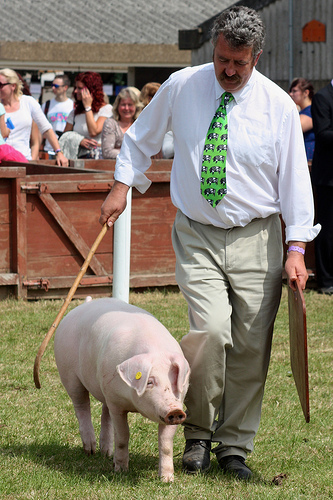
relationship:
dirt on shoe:
[188, 453, 200, 466] [181, 437, 211, 472]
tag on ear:
[134, 369, 143, 379] [113, 352, 152, 396]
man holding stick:
[121, 5, 313, 481] [83, 210, 103, 283]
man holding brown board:
[99, 5, 321, 482] [274, 251, 316, 422]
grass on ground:
[0, 281, 332, 498] [3, 284, 324, 498]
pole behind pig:
[108, 162, 145, 308] [48, 299, 191, 486]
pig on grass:
[48, 299, 191, 486] [4, 300, 327, 494]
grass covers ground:
[33, 429, 80, 492] [8, 297, 331, 493]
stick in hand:
[33, 221, 109, 389] [95, 179, 129, 226]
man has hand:
[99, 5, 321, 482] [95, 179, 129, 226]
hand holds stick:
[93, 182, 129, 226] [28, 216, 116, 390]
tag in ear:
[134, 372, 146, 379] [110, 355, 152, 394]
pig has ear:
[48, 299, 191, 486] [110, 355, 152, 394]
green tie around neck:
[197, 89, 240, 207] [201, 56, 260, 102]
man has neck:
[99, 5, 321, 482] [201, 56, 260, 102]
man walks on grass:
[99, 5, 321, 482] [273, 429, 320, 461]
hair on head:
[210, 6, 264, 53] [210, 5, 263, 92]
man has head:
[99, 5, 321, 482] [210, 5, 263, 92]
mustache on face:
[217, 67, 242, 82] [209, 27, 253, 94]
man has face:
[99, 5, 321, 482] [209, 27, 253, 94]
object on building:
[301, 18, 326, 44] [1, 2, 330, 172]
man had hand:
[99, 5, 321, 482] [91, 176, 131, 230]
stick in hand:
[33, 221, 109, 389] [91, 176, 131, 230]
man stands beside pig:
[99, 5, 321, 482] [48, 299, 191, 486]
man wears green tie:
[99, 5, 321, 482] [200, 92, 234, 209]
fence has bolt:
[3, 156, 179, 296] [16, 180, 49, 196]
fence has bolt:
[3, 156, 179, 296] [21, 275, 50, 288]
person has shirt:
[0, 67, 69, 169] [0, 94, 53, 160]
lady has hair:
[61, 67, 116, 165] [78, 68, 110, 112]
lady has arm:
[61, 67, 116, 165] [59, 125, 97, 149]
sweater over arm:
[53, 130, 83, 165] [59, 125, 97, 149]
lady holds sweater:
[61, 67, 116, 165] [53, 130, 83, 165]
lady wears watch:
[63, 72, 114, 160] [83, 105, 92, 112]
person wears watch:
[5, 70, 55, 158] [51, 146, 62, 157]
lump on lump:
[267, 466, 294, 492] [270, 471, 287, 486]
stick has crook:
[34, 221, 110, 358] [32, 353, 41, 390]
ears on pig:
[113, 352, 191, 397] [48, 299, 191, 486]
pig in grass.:
[48, 299, 191, 486] [21, 429, 87, 496]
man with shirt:
[99, 5, 321, 482] [162, 72, 302, 257]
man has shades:
[37, 70, 76, 157] [49, 82, 70, 89]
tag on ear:
[134, 369, 143, 379] [117, 353, 156, 397]